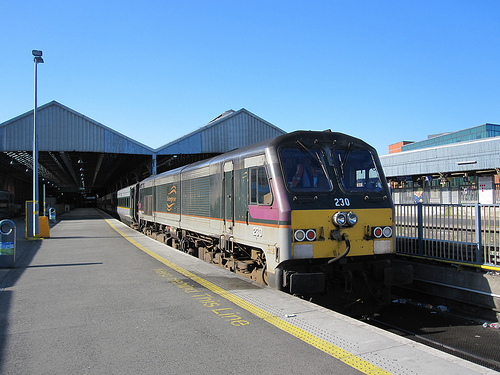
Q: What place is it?
A: It is a train station.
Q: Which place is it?
A: It is a train station.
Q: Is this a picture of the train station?
A: Yes, it is showing the train station.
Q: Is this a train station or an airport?
A: It is a train station.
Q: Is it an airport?
A: No, it is a train station.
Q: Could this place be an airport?
A: No, it is a train station.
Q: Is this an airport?
A: No, it is a train station.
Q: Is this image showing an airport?
A: No, the picture is showing a train station.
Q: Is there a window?
A: Yes, there are windows.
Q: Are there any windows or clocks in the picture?
A: Yes, there are windows.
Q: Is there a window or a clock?
A: Yes, there are windows.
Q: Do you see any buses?
A: No, there are no buses.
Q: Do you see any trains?
A: Yes, there is a train.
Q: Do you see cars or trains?
A: Yes, there is a train.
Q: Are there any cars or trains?
A: Yes, there is a train.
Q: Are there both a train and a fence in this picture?
A: Yes, there are both a train and a fence.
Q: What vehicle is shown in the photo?
A: The vehicle is a train.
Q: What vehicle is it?
A: The vehicle is a train.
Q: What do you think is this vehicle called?
A: This is a train.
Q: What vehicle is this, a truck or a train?
A: This is a train.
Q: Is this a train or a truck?
A: This is a train.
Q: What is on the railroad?
A: The train is on the railroad.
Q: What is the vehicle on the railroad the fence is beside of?
A: The vehicle is a train.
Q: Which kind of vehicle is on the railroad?
A: The vehicle is a train.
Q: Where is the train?
A: The train is on the railroad.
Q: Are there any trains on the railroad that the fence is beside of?
A: Yes, there is a train on the railroad.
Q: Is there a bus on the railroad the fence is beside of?
A: No, there is a train on the railroad.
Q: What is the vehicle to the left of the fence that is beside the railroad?
A: The vehicle is a train.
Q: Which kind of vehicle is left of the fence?
A: The vehicle is a train.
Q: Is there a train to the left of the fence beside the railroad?
A: Yes, there is a train to the left of the fence.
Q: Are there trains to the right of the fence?
A: No, the train is to the left of the fence.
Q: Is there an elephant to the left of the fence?
A: No, there is a train to the left of the fence.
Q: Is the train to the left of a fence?
A: Yes, the train is to the left of a fence.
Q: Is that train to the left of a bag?
A: No, the train is to the left of a fence.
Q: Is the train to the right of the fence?
A: No, the train is to the left of the fence.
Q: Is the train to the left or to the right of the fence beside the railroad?
A: The train is to the left of the fence.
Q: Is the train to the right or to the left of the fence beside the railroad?
A: The train is to the left of the fence.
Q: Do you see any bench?
A: No, there are no benches.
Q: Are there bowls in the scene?
A: No, there are no bowls.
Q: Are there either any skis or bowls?
A: No, there are no bowls or skis.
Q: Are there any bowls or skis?
A: No, there are no bowls or skis.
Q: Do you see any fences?
A: Yes, there is a fence.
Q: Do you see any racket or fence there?
A: Yes, there is a fence.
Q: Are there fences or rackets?
A: Yes, there is a fence.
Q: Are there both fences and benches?
A: No, there is a fence but no benches.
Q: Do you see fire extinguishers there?
A: No, there are no fire extinguishers.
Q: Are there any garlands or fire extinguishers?
A: No, there are no fire extinguishers or garlands.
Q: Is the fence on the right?
A: Yes, the fence is on the right of the image.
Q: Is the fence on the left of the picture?
A: No, the fence is on the right of the image.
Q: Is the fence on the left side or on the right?
A: The fence is on the right of the image.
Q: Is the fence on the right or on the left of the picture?
A: The fence is on the right of the image.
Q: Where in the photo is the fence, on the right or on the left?
A: The fence is on the right of the image.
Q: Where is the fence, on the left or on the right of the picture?
A: The fence is on the right of the image.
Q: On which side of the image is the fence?
A: The fence is on the right of the image.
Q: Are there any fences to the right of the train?
A: Yes, there is a fence to the right of the train.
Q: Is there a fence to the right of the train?
A: Yes, there is a fence to the right of the train.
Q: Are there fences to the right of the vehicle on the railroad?
A: Yes, there is a fence to the right of the train.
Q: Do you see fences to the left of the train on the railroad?
A: No, the fence is to the right of the train.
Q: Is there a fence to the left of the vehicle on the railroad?
A: No, the fence is to the right of the train.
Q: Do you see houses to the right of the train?
A: No, there is a fence to the right of the train.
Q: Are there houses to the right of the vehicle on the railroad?
A: No, there is a fence to the right of the train.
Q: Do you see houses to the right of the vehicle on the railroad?
A: No, there is a fence to the right of the train.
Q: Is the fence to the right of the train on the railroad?
A: Yes, the fence is to the right of the train.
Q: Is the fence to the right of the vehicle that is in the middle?
A: Yes, the fence is to the right of the train.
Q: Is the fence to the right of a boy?
A: No, the fence is to the right of the train.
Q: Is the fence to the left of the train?
A: No, the fence is to the right of the train.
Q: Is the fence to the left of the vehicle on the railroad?
A: No, the fence is to the right of the train.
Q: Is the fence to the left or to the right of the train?
A: The fence is to the right of the train.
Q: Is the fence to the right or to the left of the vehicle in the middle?
A: The fence is to the right of the train.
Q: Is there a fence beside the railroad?
A: Yes, there is a fence beside the railroad.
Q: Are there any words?
A: Yes, there are words.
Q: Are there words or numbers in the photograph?
A: Yes, there are words.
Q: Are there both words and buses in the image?
A: No, there are words but no buses.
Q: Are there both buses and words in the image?
A: No, there are words but no buses.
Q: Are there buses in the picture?
A: No, there are no buses.